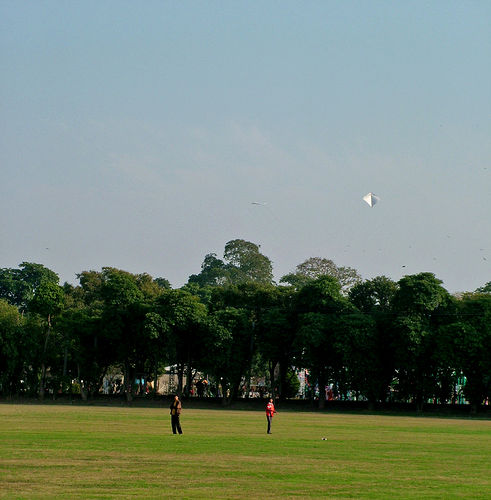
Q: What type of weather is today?
A: It is clear.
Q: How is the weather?
A: It is clear.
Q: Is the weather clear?
A: Yes, it is clear.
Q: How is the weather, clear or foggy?
A: It is clear.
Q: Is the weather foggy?
A: No, it is clear.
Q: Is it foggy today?
A: No, it is clear.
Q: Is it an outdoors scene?
A: Yes, it is outdoors.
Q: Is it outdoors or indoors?
A: It is outdoors.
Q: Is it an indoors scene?
A: No, it is outdoors.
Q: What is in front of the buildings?
A: The tree is in front of the buildings.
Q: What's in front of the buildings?
A: The tree is in front of the buildings.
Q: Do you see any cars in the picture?
A: No, there are no cars.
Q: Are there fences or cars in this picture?
A: No, there are no cars or fences.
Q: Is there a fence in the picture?
A: No, there are no fences.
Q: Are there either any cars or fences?
A: No, there are no fences or cars.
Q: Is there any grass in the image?
A: Yes, there is grass.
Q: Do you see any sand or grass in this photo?
A: Yes, there is grass.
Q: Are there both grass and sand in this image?
A: No, there is grass but no sand.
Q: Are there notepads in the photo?
A: No, there are no notepads.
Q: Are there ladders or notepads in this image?
A: No, there are no notepads or ladders.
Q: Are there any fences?
A: No, there are no fences.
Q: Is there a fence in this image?
A: No, there are no fences.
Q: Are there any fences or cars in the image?
A: No, there are no fences or cars.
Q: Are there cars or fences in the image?
A: No, there are no fences or cars.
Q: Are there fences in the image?
A: No, there are no fences.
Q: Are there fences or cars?
A: No, there are no fences or cars.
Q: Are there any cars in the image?
A: No, there are no cars.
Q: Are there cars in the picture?
A: No, there are no cars.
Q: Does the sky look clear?
A: Yes, the sky is clear.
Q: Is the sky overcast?
A: No, the sky is clear.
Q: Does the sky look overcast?
A: No, the sky is clear.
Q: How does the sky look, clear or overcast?
A: The sky is clear.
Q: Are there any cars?
A: No, there are no cars.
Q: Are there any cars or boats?
A: No, there are no cars or boats.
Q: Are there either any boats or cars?
A: No, there are no cars or boats.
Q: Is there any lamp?
A: No, there are no lamps.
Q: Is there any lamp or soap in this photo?
A: No, there are no lamps or soaps.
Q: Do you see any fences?
A: No, there are no fences.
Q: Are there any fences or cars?
A: No, there are no fences or cars.